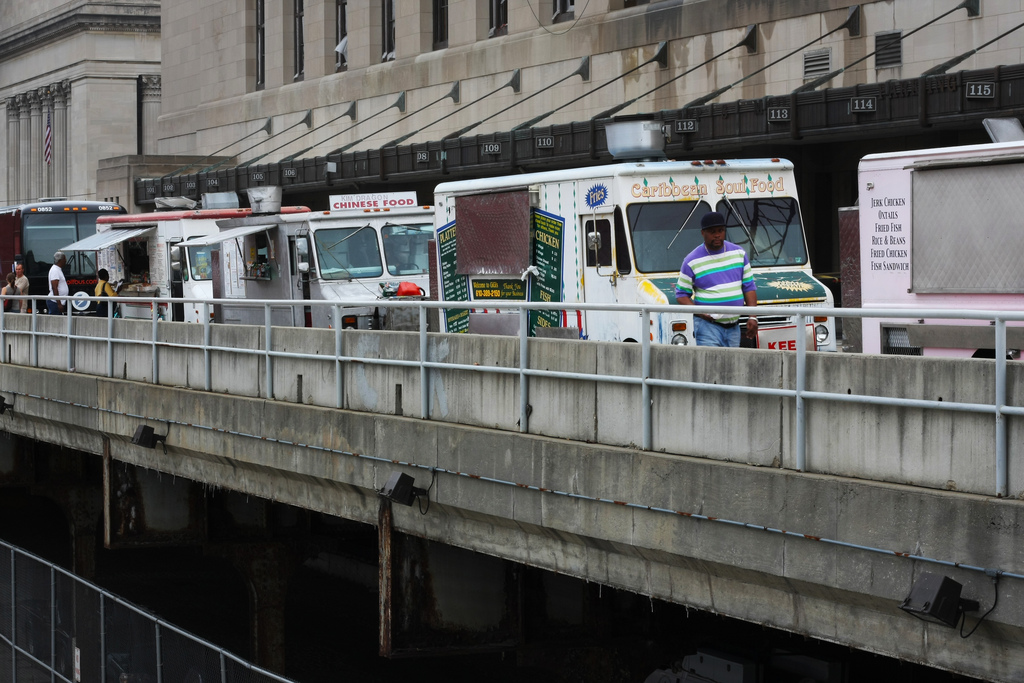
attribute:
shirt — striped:
[682, 251, 750, 309]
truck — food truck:
[429, 155, 842, 352]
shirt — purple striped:
[677, 237, 758, 326]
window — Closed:
[454, 187, 537, 281]